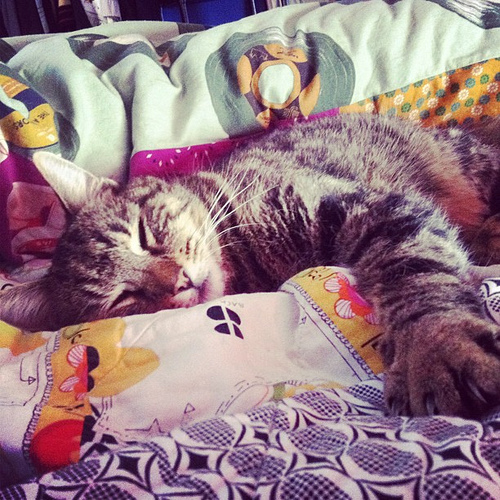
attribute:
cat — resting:
[81, 117, 498, 414]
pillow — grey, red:
[1, 0, 498, 276]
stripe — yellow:
[337, 57, 499, 141]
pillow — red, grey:
[3, 377, 499, 499]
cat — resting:
[24, 109, 496, 419]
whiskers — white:
[199, 169, 278, 253]